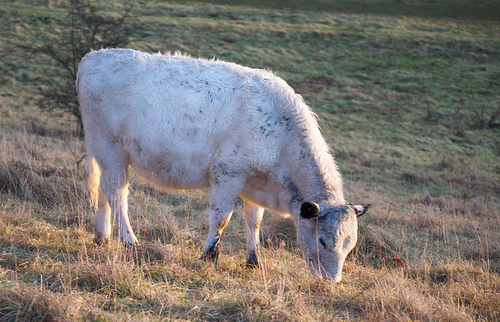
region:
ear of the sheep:
[291, 190, 318, 229]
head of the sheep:
[292, 189, 370, 280]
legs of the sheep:
[201, 195, 268, 275]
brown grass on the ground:
[117, 256, 172, 299]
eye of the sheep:
[308, 230, 327, 257]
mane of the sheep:
[255, 71, 310, 131]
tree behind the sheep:
[30, 21, 110, 46]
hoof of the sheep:
[237, 247, 260, 276]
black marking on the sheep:
[283, 173, 303, 205]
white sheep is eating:
[52, 29, 379, 309]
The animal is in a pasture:
[11, 15, 471, 310]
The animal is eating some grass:
[41, 17, 484, 300]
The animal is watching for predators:
[11, 23, 476, 310]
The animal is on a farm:
[25, 17, 451, 318]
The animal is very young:
[25, 30, 476, 305]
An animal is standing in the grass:
[26, 31, 463, 309]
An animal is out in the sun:
[17, 15, 467, 307]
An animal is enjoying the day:
[5, 27, 496, 302]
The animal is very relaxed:
[16, 10, 473, 308]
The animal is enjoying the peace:
[21, 12, 489, 315]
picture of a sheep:
[18, 25, 328, 310]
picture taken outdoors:
[13, 16, 499, 318]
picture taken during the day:
[28, 21, 495, 309]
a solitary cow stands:
[56, 36, 382, 278]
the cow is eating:
[289, 186, 377, 307]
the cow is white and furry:
[45, 51, 386, 275]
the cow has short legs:
[88, 164, 292, 284]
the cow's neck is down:
[245, 36, 370, 312]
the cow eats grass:
[60, 55, 420, 319]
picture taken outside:
[23, 30, 480, 300]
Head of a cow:
[281, 188, 379, 296]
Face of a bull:
[323, 205, 355, 292]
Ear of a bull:
[347, 194, 397, 224]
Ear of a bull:
[292, 185, 323, 230]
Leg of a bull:
[239, 186, 284, 285]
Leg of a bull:
[199, 170, 246, 278]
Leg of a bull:
[104, 136, 152, 257]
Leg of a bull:
[89, 154, 120, 268]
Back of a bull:
[83, 39, 298, 102]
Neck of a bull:
[269, 91, 321, 208]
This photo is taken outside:
[16, 17, 498, 295]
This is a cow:
[65, 38, 445, 293]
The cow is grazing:
[297, 146, 395, 261]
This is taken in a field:
[218, 2, 482, 271]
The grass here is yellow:
[57, 237, 172, 295]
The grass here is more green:
[317, 25, 472, 165]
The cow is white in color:
[60, 30, 432, 316]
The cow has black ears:
[286, 191, 367, 243]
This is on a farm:
[20, 18, 346, 309]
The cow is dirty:
[38, 44, 408, 321]